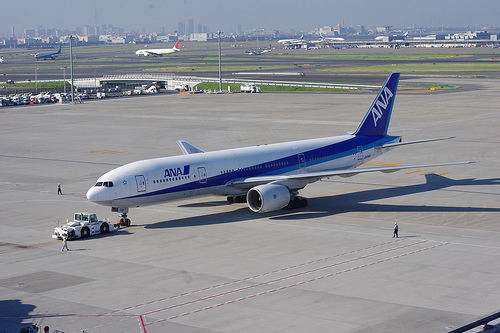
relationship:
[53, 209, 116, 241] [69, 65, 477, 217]
vehicle pulling plane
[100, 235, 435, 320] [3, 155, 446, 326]
lines on ground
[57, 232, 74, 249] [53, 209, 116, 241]
man by vehicle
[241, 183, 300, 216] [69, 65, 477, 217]
engine of plane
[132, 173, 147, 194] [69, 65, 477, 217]
door of plane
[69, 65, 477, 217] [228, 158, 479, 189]
plane with wing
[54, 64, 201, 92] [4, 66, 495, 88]
bridge on runway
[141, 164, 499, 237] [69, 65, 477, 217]
shadow of plane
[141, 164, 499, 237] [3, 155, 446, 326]
shadow on ground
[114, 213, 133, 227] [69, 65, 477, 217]
tires of plane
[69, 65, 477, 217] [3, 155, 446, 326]
plane on ground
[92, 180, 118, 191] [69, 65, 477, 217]
cockpit of plane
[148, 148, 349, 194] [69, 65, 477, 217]
windows in plane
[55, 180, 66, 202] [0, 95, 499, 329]
person walking on tarmac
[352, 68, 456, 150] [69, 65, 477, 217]
tail of plane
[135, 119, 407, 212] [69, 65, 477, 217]
fuselage of plane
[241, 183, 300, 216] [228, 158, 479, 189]
engine from wing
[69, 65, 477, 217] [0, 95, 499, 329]
plane on tarmac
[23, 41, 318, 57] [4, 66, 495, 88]
airplanes down runway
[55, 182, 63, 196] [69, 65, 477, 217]
person around plane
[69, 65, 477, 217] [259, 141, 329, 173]
plane with stripes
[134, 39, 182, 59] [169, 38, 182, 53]
airplanes with tail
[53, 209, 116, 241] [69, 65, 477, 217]
vehicle towing plane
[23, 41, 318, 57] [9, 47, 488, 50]
airplanes in background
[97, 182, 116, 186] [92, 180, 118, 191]
windows of cockpit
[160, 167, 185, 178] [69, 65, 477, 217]
ana on plane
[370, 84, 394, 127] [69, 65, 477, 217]
ana on plane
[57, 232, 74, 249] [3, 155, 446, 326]
man on ground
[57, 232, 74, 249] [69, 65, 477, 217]
man to left of plane